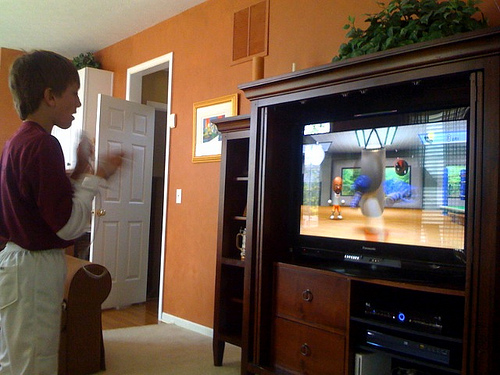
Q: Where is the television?
A: In a wooden entertainment center.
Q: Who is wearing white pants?
A: A boy.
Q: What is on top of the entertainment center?
A: Green plant.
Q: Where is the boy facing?
A: The television.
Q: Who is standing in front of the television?
A: The boy.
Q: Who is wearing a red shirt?
A: A boy.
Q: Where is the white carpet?
A: On the floor.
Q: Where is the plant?
A: Above the TV.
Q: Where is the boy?
A: In front of the TV.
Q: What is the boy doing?
A: Playing Wii.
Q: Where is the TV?
A: In front of the boy.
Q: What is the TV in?
A: TV stand.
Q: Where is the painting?
A: On the wall.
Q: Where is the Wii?
A: Below the TV.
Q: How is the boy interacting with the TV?
A: Wii remote.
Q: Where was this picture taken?
A: A living room.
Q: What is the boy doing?
A: Playing a video game.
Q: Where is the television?
A: In the entertainment center.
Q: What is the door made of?
A: Wood.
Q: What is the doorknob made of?
A: Metal.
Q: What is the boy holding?
A: A white game controller.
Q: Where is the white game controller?
A: In the hands of the boy.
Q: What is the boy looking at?
A: The television screen.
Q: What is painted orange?
A: The walls of the room.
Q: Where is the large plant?
A: On the entertainment center.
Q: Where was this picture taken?
A: Living room.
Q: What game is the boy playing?
A: Wii.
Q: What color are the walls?
A: Orange.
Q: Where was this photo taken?
A: In a living room.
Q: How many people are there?
A: One.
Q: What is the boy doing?
A: Playing a video game.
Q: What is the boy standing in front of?
A: A television.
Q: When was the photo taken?
A: Daytime.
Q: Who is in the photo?
A: A boy.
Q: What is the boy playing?
A: A video game.